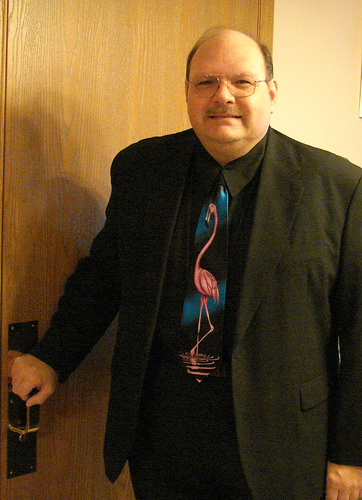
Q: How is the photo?
A: Clear.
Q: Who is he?
A: A man.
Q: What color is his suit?
A: Black.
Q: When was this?
A: Daytime.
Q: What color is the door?
A: Brown.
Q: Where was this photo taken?
A: In the office.